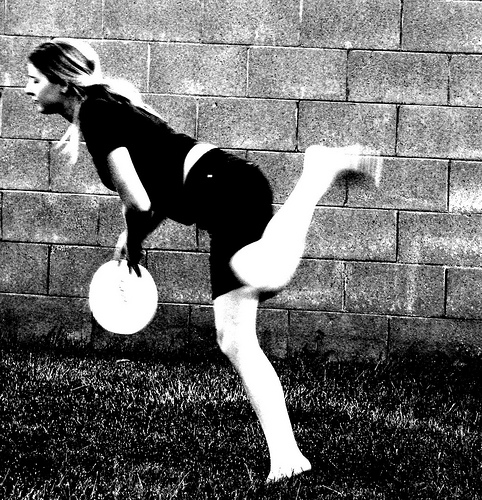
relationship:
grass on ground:
[41, 356, 176, 494] [1, 347, 466, 497]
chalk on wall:
[429, 92, 480, 264] [2, 4, 481, 387]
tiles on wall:
[169, 30, 475, 111] [2, 4, 481, 387]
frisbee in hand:
[90, 254, 157, 344] [102, 234, 151, 283]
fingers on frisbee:
[105, 243, 142, 277] [80, 252, 166, 344]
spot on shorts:
[203, 163, 233, 186] [172, 135, 286, 305]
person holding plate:
[24, 35, 386, 487] [90, 254, 157, 344]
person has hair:
[24, 35, 386, 487] [37, 37, 106, 95]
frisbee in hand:
[90, 254, 157, 344] [115, 228, 143, 273]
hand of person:
[115, 228, 143, 273] [24, 42, 386, 497]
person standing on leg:
[24, 35, 386, 487] [209, 287, 311, 491]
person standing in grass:
[24, 35, 386, 487] [4, 354, 466, 482]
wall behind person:
[160, 32, 431, 186] [24, 35, 386, 487]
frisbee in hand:
[90, 254, 157, 344] [113, 223, 141, 272]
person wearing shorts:
[24, 35, 386, 487] [180, 144, 286, 297]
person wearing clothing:
[24, 35, 386, 487] [78, 90, 199, 227]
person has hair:
[24, 42, 386, 497] [37, 37, 106, 95]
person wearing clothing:
[24, 35, 386, 487] [80, 92, 271, 296]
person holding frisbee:
[24, 35, 386, 487] [88, 257, 157, 334]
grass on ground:
[41, 356, 176, 494] [4, 353, 464, 483]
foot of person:
[302, 144, 384, 186] [24, 35, 386, 487]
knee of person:
[238, 239, 303, 298] [24, 35, 386, 487]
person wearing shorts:
[24, 35, 386, 487] [180, 149, 269, 301]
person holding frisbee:
[24, 35, 386, 487] [90, 254, 157, 344]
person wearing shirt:
[24, 35, 386, 487] [83, 98, 199, 225]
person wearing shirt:
[24, 35, 386, 487] [67, 80, 194, 226]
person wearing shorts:
[24, 35, 386, 487] [181, 146, 275, 305]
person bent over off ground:
[24, 35, 386, 487] [1, 347, 466, 497]